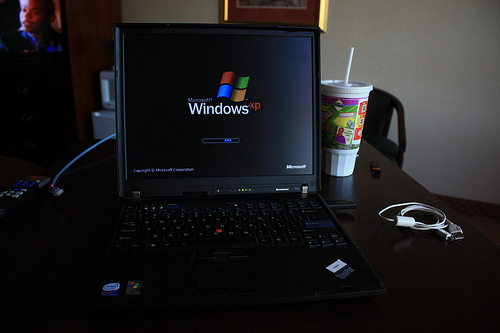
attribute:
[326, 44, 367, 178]
cup — tall, colorful, plastic, multi-colored, large, white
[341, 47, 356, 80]
straw — white, plastic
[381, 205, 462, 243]
cord — looped, white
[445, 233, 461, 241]
plugs — metal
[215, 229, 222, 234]
button — red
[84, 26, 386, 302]
laptop — open, black, plastic, on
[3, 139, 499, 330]
table — brown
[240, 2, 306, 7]
picture — framed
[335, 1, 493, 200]
wall — white, grey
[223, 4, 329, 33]
frame — golden, gold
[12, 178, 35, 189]
buttons — blue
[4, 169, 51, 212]
remote control — black, plastic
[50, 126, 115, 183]
wire — blue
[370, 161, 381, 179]
thumbdrive — black, small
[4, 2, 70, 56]
television — on